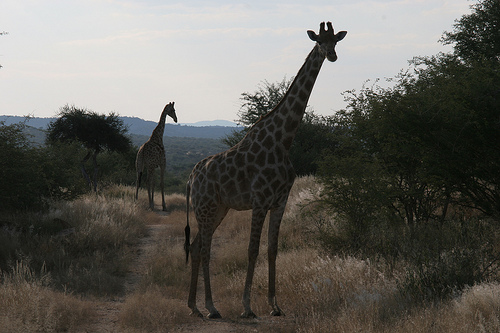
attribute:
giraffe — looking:
[134, 101, 176, 213]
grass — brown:
[55, 226, 356, 327]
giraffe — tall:
[168, 12, 339, 332]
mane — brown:
[249, 31, 320, 125]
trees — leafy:
[369, 107, 467, 199]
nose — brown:
[325, 48, 340, 66]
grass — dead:
[132, 196, 416, 325]